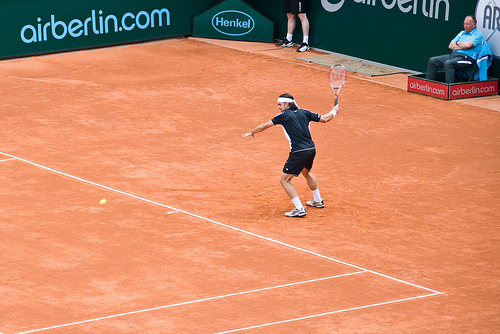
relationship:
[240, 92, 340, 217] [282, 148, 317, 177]
athlete on black shorts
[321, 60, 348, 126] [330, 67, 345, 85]
racket has w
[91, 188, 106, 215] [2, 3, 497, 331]
ball in air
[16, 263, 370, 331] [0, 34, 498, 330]
line on court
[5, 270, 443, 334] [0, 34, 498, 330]
line on court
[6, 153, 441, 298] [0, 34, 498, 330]
line on court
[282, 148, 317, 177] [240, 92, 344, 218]
black shorts on athlete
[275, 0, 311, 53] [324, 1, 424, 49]
man standing against wall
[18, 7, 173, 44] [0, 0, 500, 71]
ad on wall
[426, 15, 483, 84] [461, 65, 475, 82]
judge sitting on chair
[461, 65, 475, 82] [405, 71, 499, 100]
chair surrounded by box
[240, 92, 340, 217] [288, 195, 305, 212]
athlete wearing socks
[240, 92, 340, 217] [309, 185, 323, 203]
athlete wearing socks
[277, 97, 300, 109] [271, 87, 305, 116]
headband on player's head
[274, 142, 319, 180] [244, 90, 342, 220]
black shorts on player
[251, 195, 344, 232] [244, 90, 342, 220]
socks on player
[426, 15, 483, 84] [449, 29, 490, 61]
judge wearing shirt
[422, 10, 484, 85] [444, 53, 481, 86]
judge sitting in chair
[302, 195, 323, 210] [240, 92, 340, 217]
shoe on athlete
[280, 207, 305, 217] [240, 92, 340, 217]
shoe on athlete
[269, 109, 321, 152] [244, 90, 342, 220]
shirt on player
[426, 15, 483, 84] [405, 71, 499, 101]
judge watching box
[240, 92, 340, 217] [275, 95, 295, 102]
athlete wearing headband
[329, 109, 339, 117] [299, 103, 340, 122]
wristband on arm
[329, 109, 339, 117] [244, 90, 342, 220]
wristband on player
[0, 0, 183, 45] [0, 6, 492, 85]
ad on wall